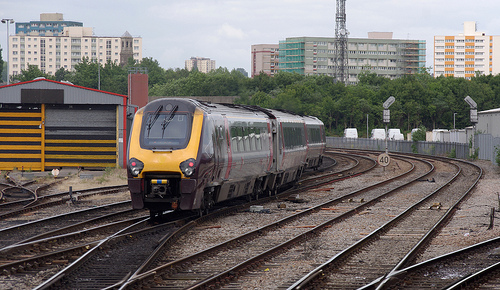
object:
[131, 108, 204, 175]
paint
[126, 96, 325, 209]
train